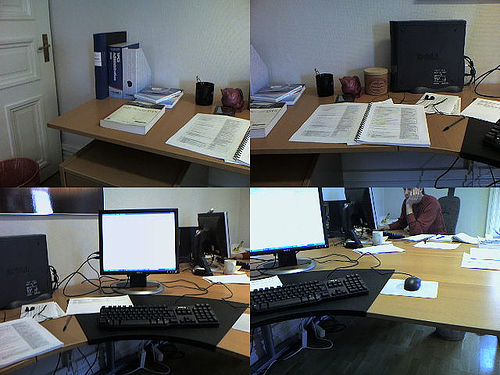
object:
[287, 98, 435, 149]
book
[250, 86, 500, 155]
table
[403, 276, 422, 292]
mouse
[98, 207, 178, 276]
monitor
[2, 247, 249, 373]
desk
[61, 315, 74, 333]
pen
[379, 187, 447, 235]
man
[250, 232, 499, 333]
desk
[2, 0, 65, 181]
door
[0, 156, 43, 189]
can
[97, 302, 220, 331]
keyboard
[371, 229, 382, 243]
cup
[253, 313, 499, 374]
floor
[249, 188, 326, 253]
screen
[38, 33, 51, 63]
handle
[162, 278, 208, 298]
wire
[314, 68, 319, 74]
pencil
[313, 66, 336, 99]
holder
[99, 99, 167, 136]
book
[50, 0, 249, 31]
wall